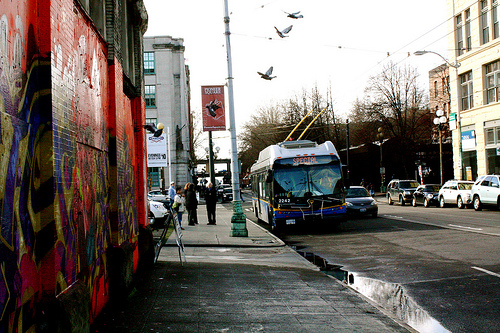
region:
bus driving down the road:
[248, 130, 390, 241]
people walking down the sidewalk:
[165, 176, 231, 229]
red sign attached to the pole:
[196, 78, 239, 133]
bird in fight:
[254, 64, 275, 85]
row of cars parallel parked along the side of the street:
[387, 173, 499, 218]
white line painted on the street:
[462, 253, 499, 287]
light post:
[411, 42, 469, 192]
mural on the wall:
[0, 3, 151, 331]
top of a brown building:
[423, 61, 450, 111]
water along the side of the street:
[336, 258, 435, 332]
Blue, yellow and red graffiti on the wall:
[33, 73, 165, 272]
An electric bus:
[241, 122, 331, 227]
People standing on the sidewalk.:
[166, 175, 221, 220]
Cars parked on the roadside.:
[390, 176, 497, 213]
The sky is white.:
[345, 19, 405, 80]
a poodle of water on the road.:
[376, 281, 406, 309]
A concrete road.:
[408, 217, 471, 274]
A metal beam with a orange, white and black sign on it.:
[223, 17, 245, 222]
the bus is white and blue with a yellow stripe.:
[255, 140, 329, 250]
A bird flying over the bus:
[255, 66, 287, 98]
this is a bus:
[257, 145, 349, 222]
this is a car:
[473, 179, 495, 192]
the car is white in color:
[481, 186, 497, 202]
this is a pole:
[225, 32, 245, 203]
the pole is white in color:
[226, 95, 236, 121]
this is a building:
[451, 33, 498, 101]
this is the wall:
[473, 110, 499, 125]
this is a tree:
[376, 73, 416, 115]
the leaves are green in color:
[361, 105, 379, 125]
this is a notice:
[206, 87, 228, 122]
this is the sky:
[305, 31, 321, 67]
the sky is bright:
[300, 45, 325, 70]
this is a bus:
[246, 135, 341, 220]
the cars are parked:
[380, 175, 497, 205]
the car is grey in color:
[445, 190, 451, 201]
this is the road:
[396, 227, 464, 269]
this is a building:
[145, 32, 191, 173]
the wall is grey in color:
[155, 36, 188, 197]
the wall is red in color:
[108, 78, 125, 125]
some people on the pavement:
[170, 182, 216, 227]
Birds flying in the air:
[252, 58, 279, 83]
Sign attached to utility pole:
[191, 77, 231, 134]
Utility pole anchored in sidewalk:
[211, 17, 254, 239]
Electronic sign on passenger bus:
[277, 154, 333, 166]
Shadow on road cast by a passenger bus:
[337, 211, 459, 229]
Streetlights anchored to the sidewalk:
[429, 102, 451, 206]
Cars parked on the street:
[387, 170, 498, 215]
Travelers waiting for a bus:
[179, 177, 227, 228]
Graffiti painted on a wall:
[7, 11, 144, 298]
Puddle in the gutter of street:
[305, 250, 458, 331]